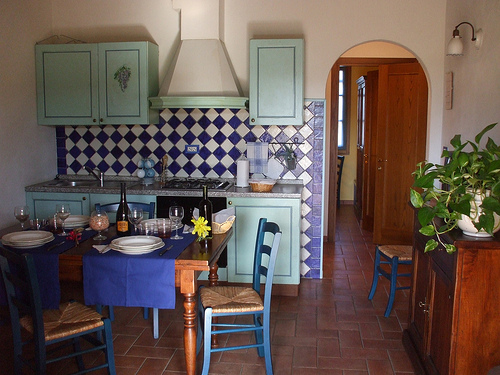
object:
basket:
[220, 168, 287, 200]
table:
[0, 215, 231, 274]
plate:
[110, 237, 165, 254]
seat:
[193, 281, 262, 312]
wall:
[0, 0, 499, 282]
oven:
[155, 194, 230, 271]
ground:
[385, 93, 403, 127]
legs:
[380, 262, 400, 318]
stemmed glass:
[116, 181, 133, 239]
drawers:
[38, 51, 90, 118]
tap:
[81, 165, 105, 188]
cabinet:
[37, 42, 100, 124]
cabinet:
[99, 40, 159, 125]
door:
[368, 61, 428, 250]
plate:
[4, 230, 55, 242]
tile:
[336, 303, 354, 315]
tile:
[339, 330, 364, 348]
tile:
[294, 344, 317, 366]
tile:
[295, 325, 337, 339]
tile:
[358, 320, 383, 340]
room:
[333, 77, 414, 241]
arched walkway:
[320, 38, 429, 245]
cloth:
[84, 226, 197, 310]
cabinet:
[249, 36, 304, 125]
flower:
[405, 121, 497, 258]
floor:
[266, 203, 423, 374]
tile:
[317, 337, 340, 359]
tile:
[317, 317, 359, 329]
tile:
[296, 317, 315, 328]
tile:
[316, 356, 366, 371]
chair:
[193, 217, 281, 374]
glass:
[156, 217, 173, 238]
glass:
[140, 220, 153, 235]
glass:
[168, 206, 184, 240]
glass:
[127, 207, 143, 235]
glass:
[55, 204, 71, 235]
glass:
[12, 205, 29, 229]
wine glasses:
[168, 205, 186, 242]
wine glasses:
[125, 208, 143, 235]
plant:
[410, 119, 499, 254]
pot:
[452, 186, 499, 238]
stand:
[400, 208, 499, 373]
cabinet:
[399, 221, 498, 373]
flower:
[189, 215, 212, 240]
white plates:
[59, 213, 89, 229]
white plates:
[139, 218, 183, 233]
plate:
[110, 235, 162, 247]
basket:
[246, 178, 275, 191]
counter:
[25, 177, 307, 299]